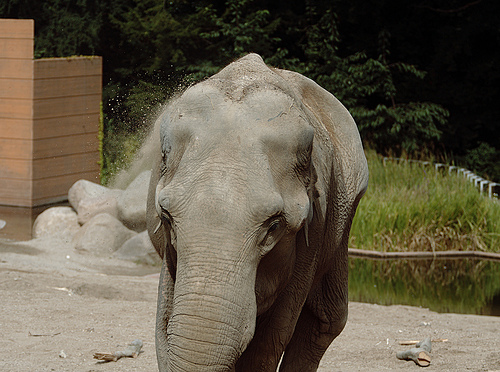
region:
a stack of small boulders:
[33, 177, 157, 270]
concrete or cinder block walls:
[2, 20, 104, 205]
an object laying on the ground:
[395, 337, 430, 368]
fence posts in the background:
[382, 155, 498, 204]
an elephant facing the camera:
[147, 51, 367, 370]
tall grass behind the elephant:
[352, 151, 497, 312]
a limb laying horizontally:
[348, 242, 498, 260]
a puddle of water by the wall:
[0, 206, 43, 257]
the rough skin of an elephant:
[176, 221, 238, 355]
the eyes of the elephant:
[147, 203, 290, 248]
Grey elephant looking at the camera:
[126, 47, 354, 371]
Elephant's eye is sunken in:
[249, 199, 289, 249]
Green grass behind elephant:
[356, 138, 496, 309]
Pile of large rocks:
[35, 167, 160, 284]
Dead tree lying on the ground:
[347, 228, 495, 275]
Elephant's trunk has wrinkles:
[146, 231, 270, 371]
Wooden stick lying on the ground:
[90, 342, 135, 369]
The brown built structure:
[0, 20, 100, 240]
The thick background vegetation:
[0, 0, 497, 197]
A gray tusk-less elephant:
[146, 52, 368, 370]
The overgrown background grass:
[102, 113, 498, 313]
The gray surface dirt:
[0, 242, 498, 370]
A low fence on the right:
[389, 150, 499, 199]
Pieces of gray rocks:
[35, 170, 163, 270]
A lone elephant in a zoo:
[0, 0, 497, 371]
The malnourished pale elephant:
[139, 55, 369, 370]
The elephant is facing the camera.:
[145, 51, 370, 370]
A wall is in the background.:
[0, 18, 102, 174]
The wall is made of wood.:
[0, 18, 100, 176]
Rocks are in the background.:
[35, 179, 145, 251]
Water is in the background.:
[360, 258, 494, 300]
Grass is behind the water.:
[374, 191, 487, 248]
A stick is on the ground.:
[93, 338, 142, 361]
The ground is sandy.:
[0, 289, 131, 329]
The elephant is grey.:
[179, 98, 290, 201]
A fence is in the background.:
[459, 166, 499, 197]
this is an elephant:
[106, 60, 354, 365]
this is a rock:
[76, 210, 133, 260]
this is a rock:
[36, 201, 78, 251]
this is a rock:
[68, 176, 120, 218]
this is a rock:
[115, 176, 174, 231]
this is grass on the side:
[378, 152, 426, 225]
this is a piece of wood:
[85, 318, 155, 368]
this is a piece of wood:
[393, 325, 443, 370]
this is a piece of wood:
[370, 233, 493, 269]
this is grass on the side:
[369, 156, 426, 218]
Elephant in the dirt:
[103, 46, 386, 368]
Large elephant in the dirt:
[92, 63, 406, 364]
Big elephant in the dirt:
[121, 67, 396, 362]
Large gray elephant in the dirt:
[138, 66, 382, 363]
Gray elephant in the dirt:
[108, 67, 389, 360]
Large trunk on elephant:
[147, 255, 279, 370]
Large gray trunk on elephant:
[151, 249, 291, 369]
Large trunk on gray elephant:
[167, 255, 281, 367]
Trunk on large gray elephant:
[145, 256, 272, 370]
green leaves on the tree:
[408, 119, 438, 144]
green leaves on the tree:
[375, 103, 404, 135]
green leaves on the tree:
[390, 86, 397, 118]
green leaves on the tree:
[225, 12, 282, 35]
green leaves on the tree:
[156, 30, 193, 76]